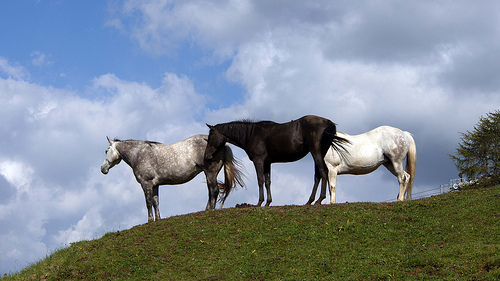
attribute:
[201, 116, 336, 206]
horse — black, dark bay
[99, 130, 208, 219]
horse — gray, standing, white, dappled gray, an appaloosa, bulky, grey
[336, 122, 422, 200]
horse — white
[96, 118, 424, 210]
horses — in same direction, light colored, magnificent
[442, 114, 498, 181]
tree — in the distance, on the hill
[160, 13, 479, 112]
clouds — white, puffy, dark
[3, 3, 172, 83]
sky — blue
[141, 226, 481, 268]
grass — green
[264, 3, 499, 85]
storm — coming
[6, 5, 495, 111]
background — blue